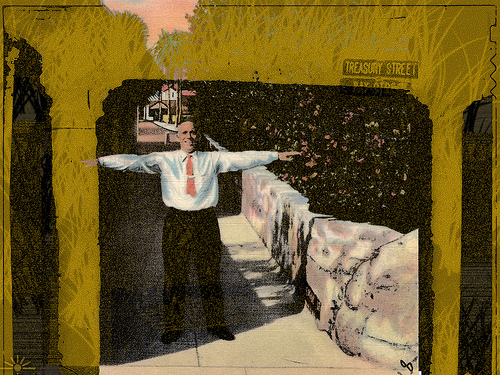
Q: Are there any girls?
A: No, there are no girls.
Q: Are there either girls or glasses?
A: No, there are no girls or glasses.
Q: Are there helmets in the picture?
A: No, there are no helmets.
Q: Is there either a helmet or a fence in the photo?
A: No, there are no helmets or fences.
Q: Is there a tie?
A: Yes, there is a tie.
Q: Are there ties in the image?
A: Yes, there is a tie.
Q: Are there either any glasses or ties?
A: Yes, there is a tie.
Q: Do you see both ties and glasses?
A: No, there is a tie but no glasses.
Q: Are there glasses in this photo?
A: No, there are no glasses.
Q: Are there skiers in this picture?
A: No, there are no skiers.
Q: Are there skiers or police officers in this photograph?
A: No, there are no skiers or police officers.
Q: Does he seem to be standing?
A: Yes, the man is standing.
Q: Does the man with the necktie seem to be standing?
A: Yes, the man is standing.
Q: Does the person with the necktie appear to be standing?
A: Yes, the man is standing.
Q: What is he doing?
A: The man is standing.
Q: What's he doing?
A: The man is standing.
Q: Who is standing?
A: The man is standing.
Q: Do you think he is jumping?
A: No, the man is standing.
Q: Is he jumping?
A: No, the man is standing.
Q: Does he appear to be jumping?
A: No, the man is standing.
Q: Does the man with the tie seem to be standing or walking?
A: The man is standing.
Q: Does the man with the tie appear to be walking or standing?
A: The man is standing.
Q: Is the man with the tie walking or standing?
A: The man is standing.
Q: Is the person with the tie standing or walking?
A: The man is standing.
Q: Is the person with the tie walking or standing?
A: The man is standing.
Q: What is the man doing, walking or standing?
A: The man is standing.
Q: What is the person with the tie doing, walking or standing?
A: The man is standing.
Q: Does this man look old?
A: Yes, the man is old.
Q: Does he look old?
A: Yes, the man is old.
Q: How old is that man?
A: The man is old.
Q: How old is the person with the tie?
A: The man is old.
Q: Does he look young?
A: No, the man is old.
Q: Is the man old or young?
A: The man is old.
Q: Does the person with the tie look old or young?
A: The man is old.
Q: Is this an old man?
A: Yes, this is an old man.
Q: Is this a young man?
A: No, this is an old man.